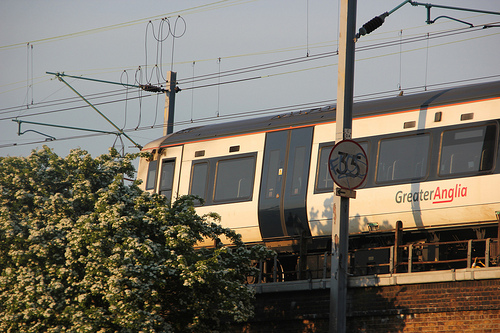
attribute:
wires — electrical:
[6, 7, 481, 143]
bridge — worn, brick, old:
[173, 228, 484, 319]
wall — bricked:
[228, 264, 496, 329]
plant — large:
[2, 144, 262, 330]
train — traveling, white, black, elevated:
[127, 74, 499, 255]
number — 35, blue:
[339, 145, 364, 182]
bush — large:
[2, 149, 277, 331]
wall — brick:
[244, 278, 500, 328]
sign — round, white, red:
[390, 184, 473, 206]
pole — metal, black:
[328, 5, 362, 333]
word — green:
[391, 186, 432, 205]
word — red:
[432, 186, 473, 202]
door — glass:
[257, 123, 313, 243]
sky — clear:
[2, 2, 497, 153]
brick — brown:
[354, 290, 495, 333]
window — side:
[141, 157, 174, 187]